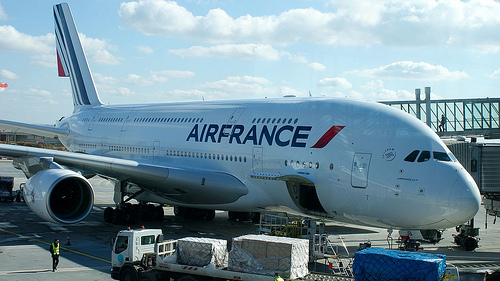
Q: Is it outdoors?
A: Yes, it is outdoors.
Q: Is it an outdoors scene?
A: Yes, it is outdoors.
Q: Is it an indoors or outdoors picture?
A: It is outdoors.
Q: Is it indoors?
A: No, it is outdoors.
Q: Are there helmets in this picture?
A: No, there are no helmets.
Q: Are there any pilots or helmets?
A: No, there are no helmets or pilots.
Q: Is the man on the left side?
A: Yes, the man is on the left of the image.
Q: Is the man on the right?
A: No, the man is on the left of the image.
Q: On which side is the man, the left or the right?
A: The man is on the left of the image.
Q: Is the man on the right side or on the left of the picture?
A: The man is on the left of the image.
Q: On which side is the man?
A: The man is on the left of the image.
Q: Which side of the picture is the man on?
A: The man is on the left of the image.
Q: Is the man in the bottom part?
A: Yes, the man is in the bottom of the image.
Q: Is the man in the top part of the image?
A: No, the man is in the bottom of the image.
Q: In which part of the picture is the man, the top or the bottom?
A: The man is in the bottom of the image.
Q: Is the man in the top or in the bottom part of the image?
A: The man is in the bottom of the image.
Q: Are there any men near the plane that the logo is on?
A: Yes, there is a man near the airplane.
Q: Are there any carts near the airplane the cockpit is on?
A: No, there is a man near the plane.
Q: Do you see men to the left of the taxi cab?
A: Yes, there is a man to the left of the taxi cab.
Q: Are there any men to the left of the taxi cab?
A: Yes, there is a man to the left of the taxi cab.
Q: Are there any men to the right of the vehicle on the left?
A: No, the man is to the left of the taxi cab.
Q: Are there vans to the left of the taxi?
A: No, there is a man to the left of the taxi.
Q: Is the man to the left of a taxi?
A: Yes, the man is to the left of a taxi.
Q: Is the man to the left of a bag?
A: No, the man is to the left of a taxi.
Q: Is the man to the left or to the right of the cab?
A: The man is to the left of the cab.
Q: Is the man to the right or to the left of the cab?
A: The man is to the left of the cab.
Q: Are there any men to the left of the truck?
A: Yes, there is a man to the left of the truck.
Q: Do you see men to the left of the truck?
A: Yes, there is a man to the left of the truck.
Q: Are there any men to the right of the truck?
A: No, the man is to the left of the truck.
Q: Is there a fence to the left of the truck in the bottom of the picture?
A: No, there is a man to the left of the truck.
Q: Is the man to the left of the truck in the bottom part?
A: Yes, the man is to the left of the truck.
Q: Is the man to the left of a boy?
A: No, the man is to the left of the truck.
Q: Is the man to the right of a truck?
A: No, the man is to the left of a truck.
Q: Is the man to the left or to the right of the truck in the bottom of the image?
A: The man is to the left of the truck.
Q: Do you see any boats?
A: No, there are no boats.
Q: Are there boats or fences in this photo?
A: No, there are no boats or fences.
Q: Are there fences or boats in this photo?
A: No, there are no boats or fences.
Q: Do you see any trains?
A: No, there are no trains.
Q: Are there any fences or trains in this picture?
A: No, there are no trains or fences.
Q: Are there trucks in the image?
A: Yes, there is a truck.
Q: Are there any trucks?
A: Yes, there is a truck.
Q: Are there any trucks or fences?
A: Yes, there is a truck.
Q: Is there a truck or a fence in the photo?
A: Yes, there is a truck.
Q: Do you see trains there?
A: No, there are no trains.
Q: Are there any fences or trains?
A: No, there are no trains or fences.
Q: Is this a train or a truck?
A: This is a truck.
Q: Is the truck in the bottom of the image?
A: Yes, the truck is in the bottom of the image.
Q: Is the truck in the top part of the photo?
A: No, the truck is in the bottom of the image.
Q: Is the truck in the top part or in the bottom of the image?
A: The truck is in the bottom of the image.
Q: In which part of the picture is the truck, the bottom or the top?
A: The truck is in the bottom of the image.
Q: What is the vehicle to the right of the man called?
A: The vehicle is a truck.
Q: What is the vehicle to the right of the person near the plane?
A: The vehicle is a truck.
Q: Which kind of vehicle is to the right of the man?
A: The vehicle is a truck.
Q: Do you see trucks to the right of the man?
A: Yes, there is a truck to the right of the man.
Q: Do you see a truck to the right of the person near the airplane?
A: Yes, there is a truck to the right of the man.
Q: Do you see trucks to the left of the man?
A: No, the truck is to the right of the man.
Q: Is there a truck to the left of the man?
A: No, the truck is to the right of the man.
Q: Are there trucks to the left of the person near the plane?
A: No, the truck is to the right of the man.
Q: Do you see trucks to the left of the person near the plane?
A: No, the truck is to the right of the man.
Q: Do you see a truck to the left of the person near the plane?
A: No, the truck is to the right of the man.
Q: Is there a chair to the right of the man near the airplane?
A: No, there is a truck to the right of the man.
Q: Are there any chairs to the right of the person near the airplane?
A: No, there is a truck to the right of the man.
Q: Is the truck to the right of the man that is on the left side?
A: Yes, the truck is to the right of the man.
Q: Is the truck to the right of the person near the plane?
A: Yes, the truck is to the right of the man.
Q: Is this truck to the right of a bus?
A: No, the truck is to the right of the man.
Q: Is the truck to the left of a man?
A: No, the truck is to the right of a man.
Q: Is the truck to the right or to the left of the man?
A: The truck is to the right of the man.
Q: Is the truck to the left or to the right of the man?
A: The truck is to the right of the man.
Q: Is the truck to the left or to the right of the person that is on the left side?
A: The truck is to the right of the man.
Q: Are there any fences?
A: No, there are no fences.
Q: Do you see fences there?
A: No, there are no fences.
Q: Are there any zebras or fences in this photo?
A: No, there are no fences or zebras.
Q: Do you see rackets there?
A: No, there are no rackets.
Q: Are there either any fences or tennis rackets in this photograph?
A: No, there are no tennis rackets or fences.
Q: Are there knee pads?
A: No, there are no knee pads.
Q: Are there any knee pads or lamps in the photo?
A: No, there are no knee pads or lamps.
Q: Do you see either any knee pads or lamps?
A: No, there are no knee pads or lamps.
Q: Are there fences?
A: No, there are no fences.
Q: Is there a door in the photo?
A: Yes, there is a door.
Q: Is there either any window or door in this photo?
A: Yes, there is a door.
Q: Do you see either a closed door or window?
A: Yes, there is a closed door.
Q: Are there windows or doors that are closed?
A: Yes, the door is closed.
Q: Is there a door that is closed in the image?
A: Yes, there is a closed door.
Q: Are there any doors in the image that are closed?
A: Yes, there is a door that is closed.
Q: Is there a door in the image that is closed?
A: Yes, there is a door that is closed.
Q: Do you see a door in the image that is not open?
A: Yes, there is an closed door.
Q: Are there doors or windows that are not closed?
A: No, there is a door but it is closed.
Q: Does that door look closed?
A: Yes, the door is closed.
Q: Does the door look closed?
A: Yes, the door is closed.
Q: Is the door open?
A: No, the door is closed.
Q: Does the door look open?
A: No, the door is closed.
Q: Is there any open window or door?
A: No, there is a door but it is closed.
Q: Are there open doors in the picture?
A: No, there is a door but it is closed.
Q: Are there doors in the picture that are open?
A: No, there is a door but it is closed.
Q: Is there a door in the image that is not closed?
A: No, there is a door but it is closed.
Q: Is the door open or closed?
A: The door is closed.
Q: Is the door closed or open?
A: The door is closed.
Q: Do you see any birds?
A: No, there are no birds.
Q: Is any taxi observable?
A: Yes, there is a taxi.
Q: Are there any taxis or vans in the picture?
A: Yes, there is a taxi.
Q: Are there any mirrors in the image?
A: No, there are no mirrors.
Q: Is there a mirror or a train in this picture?
A: No, there are no mirrors or trains.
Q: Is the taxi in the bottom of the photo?
A: Yes, the taxi is in the bottom of the image.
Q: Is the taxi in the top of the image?
A: No, the taxi is in the bottom of the image.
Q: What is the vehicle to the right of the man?
A: The vehicle is a taxi.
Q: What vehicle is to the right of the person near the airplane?
A: The vehicle is a taxi.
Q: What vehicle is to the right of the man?
A: The vehicle is a taxi.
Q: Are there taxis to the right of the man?
A: Yes, there is a taxi to the right of the man.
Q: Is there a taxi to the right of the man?
A: Yes, there is a taxi to the right of the man.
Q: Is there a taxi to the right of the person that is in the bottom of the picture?
A: Yes, there is a taxi to the right of the man.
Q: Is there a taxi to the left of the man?
A: No, the taxi is to the right of the man.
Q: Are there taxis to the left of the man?
A: No, the taxi is to the right of the man.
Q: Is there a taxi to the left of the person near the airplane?
A: No, the taxi is to the right of the man.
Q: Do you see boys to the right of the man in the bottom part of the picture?
A: No, there is a taxi to the right of the man.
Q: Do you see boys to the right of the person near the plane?
A: No, there is a taxi to the right of the man.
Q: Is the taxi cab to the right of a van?
A: No, the taxi cab is to the right of a man.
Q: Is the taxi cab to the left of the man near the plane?
A: No, the taxi cab is to the right of the man.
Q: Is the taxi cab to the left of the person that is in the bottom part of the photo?
A: No, the taxi cab is to the right of the man.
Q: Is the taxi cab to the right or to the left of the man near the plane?
A: The taxi cab is to the right of the man.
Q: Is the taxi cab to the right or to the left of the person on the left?
A: The taxi cab is to the right of the man.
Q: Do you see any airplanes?
A: Yes, there is an airplane.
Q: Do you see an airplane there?
A: Yes, there is an airplane.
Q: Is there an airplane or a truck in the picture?
A: Yes, there is an airplane.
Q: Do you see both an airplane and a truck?
A: Yes, there are both an airplane and a truck.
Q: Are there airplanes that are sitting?
A: Yes, there is an airplane that is sitting.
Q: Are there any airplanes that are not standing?
A: Yes, there is an airplane that is sitting.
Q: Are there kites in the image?
A: No, there are no kites.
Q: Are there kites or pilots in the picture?
A: No, there are no kites or pilots.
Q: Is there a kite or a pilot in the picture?
A: No, there are no kites or pilots.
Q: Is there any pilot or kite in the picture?
A: No, there are no kites or pilots.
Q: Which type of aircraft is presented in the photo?
A: The aircraft is an airplane.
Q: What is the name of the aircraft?
A: The aircraft is an airplane.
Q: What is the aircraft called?
A: The aircraft is an airplane.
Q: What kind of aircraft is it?
A: The aircraft is an airplane.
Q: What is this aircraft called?
A: This is an airplane.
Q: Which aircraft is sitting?
A: The aircraft is an airplane.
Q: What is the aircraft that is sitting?
A: The aircraft is an airplane.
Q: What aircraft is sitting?
A: The aircraft is an airplane.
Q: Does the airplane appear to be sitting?
A: Yes, the airplane is sitting.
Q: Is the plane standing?
A: No, the plane is sitting.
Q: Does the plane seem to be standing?
A: No, the plane is sitting.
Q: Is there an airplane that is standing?
A: No, there is an airplane but it is sitting.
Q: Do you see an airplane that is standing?
A: No, there is an airplane but it is sitting.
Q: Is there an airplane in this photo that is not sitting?
A: No, there is an airplane but it is sitting.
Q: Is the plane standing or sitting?
A: The plane is sitting.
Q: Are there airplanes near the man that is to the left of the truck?
A: Yes, there is an airplane near the man.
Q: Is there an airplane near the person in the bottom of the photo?
A: Yes, there is an airplane near the man.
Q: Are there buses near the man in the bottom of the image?
A: No, there is an airplane near the man.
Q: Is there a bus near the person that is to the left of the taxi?
A: No, there is an airplane near the man.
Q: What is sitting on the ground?
A: The airplane is sitting on the ground.